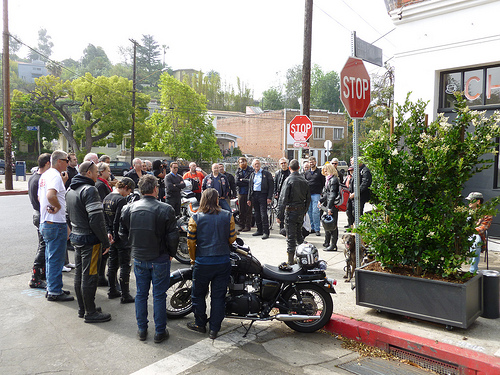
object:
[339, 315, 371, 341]
paint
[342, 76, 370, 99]
stop sign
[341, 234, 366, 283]
dog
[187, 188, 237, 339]
woman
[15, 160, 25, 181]
mailbox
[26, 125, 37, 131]
sign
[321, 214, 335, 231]
helmet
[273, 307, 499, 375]
curb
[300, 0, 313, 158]
post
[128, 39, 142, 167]
post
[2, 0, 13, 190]
post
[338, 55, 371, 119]
sign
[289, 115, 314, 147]
sign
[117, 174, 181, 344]
man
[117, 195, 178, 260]
jacket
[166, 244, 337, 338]
motorcycle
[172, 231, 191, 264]
wheel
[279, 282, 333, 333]
wheel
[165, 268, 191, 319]
wheel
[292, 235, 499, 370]
sidewalk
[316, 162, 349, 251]
woman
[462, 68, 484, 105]
window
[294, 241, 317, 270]
helmet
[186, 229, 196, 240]
blue strips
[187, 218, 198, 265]
sleeve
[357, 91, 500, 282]
shrub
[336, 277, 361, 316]
corner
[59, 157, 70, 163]
sunglasses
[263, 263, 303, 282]
seat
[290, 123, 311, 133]
stop sign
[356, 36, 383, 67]
sign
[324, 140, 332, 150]
back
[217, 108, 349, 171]
building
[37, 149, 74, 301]
man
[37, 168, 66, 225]
shirt